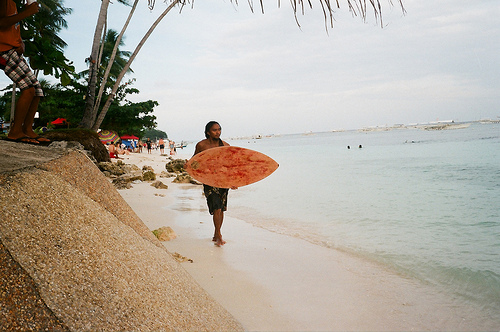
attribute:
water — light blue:
[178, 120, 498, 329]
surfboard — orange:
[182, 144, 279, 189]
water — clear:
[341, 152, 475, 263]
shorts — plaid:
[0, 46, 65, 117]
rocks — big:
[108, 199, 235, 307]